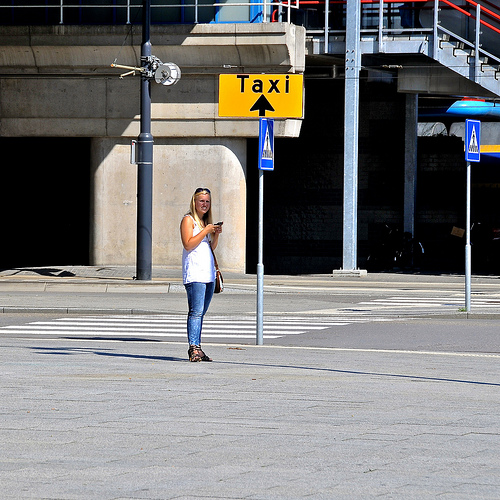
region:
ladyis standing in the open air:
[143, 168, 265, 360]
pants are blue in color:
[181, 283, 236, 352]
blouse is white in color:
[176, 226, 234, 271]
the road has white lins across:
[296, 287, 409, 335]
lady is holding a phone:
[157, 190, 277, 315]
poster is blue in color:
[247, 108, 287, 176]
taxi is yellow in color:
[239, 57, 310, 132]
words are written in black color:
[231, 73, 285, 105]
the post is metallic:
[234, 172, 292, 351]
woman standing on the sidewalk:
[173, 182, 227, 377]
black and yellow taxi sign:
[210, 65, 311, 127]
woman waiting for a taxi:
[169, 65, 311, 370]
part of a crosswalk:
[2, 299, 462, 339]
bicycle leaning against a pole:
[368, 216, 431, 276]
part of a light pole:
[108, 31, 168, 281]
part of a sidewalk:
[19, 263, 133, 288]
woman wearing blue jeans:
[175, 180, 228, 370]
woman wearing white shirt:
[175, 183, 225, 368]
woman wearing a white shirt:
[174, 207, 226, 284]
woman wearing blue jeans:
[180, 274, 217, 345]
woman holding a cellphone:
[206, 216, 227, 231]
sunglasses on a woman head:
[188, 180, 213, 202]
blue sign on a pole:
[254, 107, 293, 183]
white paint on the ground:
[61, 291, 316, 352]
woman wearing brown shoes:
[171, 340, 223, 372]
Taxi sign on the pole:
[215, 64, 317, 126]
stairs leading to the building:
[371, 0, 496, 75]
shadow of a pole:
[24, 253, 87, 288]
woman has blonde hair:
[186, 182, 213, 233]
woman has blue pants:
[185, 275, 220, 350]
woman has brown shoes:
[170, 341, 216, 377]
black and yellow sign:
[220, 60, 301, 125]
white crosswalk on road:
[1, 262, 436, 329]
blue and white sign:
[251, 118, 281, 175]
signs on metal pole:
[197, 65, 277, 343]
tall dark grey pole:
[123, 11, 173, 287]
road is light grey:
[362, 308, 488, 360]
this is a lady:
[169, 177, 235, 363]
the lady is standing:
[156, 181, 241, 358]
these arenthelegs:
[184, 282, 219, 349]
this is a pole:
[244, 198, 273, 343]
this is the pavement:
[174, 376, 374, 493]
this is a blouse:
[182, 250, 212, 280]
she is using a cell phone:
[203, 213, 227, 234]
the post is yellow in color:
[221, 75, 293, 115]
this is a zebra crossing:
[316, 280, 391, 332]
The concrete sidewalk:
[6, 332, 493, 499]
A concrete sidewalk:
[6, 330, 495, 488]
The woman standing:
[174, 178, 239, 362]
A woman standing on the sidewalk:
[173, 182, 244, 366]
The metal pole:
[242, 166, 279, 343]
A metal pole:
[250, 168, 282, 340]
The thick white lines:
[4, 299, 369, 343]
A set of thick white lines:
[5, 296, 367, 349]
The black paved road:
[3, 305, 495, 356]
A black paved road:
[6, 290, 498, 372]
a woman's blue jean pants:
[182, 281, 217, 343]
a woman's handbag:
[205, 225, 222, 295]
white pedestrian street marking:
[0, 283, 485, 364]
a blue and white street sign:
[257, 118, 277, 170]